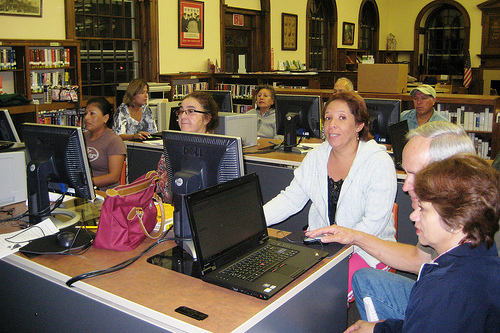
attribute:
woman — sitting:
[345, 157, 500, 332]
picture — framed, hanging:
[176, 1, 208, 52]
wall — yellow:
[1, 4, 398, 89]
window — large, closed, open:
[68, 0, 160, 107]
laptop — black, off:
[179, 173, 326, 298]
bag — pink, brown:
[96, 162, 166, 251]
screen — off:
[183, 173, 271, 265]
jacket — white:
[264, 140, 399, 241]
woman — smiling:
[257, 91, 396, 246]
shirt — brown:
[83, 130, 128, 181]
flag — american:
[459, 42, 474, 96]